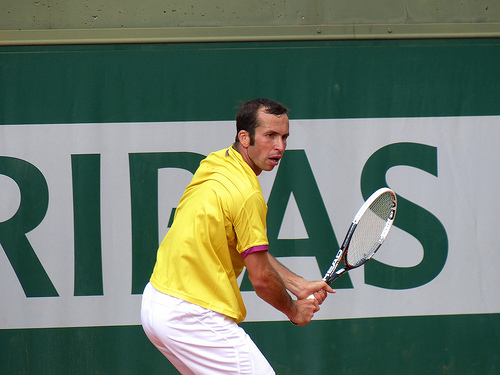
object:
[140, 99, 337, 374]
man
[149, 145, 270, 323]
t-shirt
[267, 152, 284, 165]
mouth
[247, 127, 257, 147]
sideburn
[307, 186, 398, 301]
racket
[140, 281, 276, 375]
pants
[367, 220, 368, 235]
tennis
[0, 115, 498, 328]
sign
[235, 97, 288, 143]
hair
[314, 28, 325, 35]
bolt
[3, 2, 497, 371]
wall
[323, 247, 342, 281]
writing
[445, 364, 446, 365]
ball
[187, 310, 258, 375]
seam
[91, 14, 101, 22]
hole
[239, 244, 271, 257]
pink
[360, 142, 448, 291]
s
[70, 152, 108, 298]
i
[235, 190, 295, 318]
right arm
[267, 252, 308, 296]
left arm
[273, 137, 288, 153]
nose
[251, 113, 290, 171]
face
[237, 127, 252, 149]
ear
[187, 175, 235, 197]
wrinkles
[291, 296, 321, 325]
hands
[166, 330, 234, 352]
wrinkles